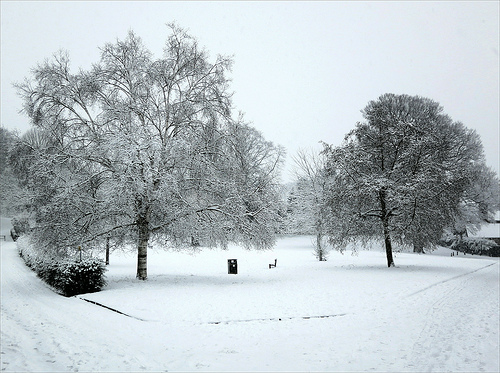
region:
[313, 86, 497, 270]
tree covered with snow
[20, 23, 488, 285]
two trees covered with snow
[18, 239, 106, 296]
low shrub with snow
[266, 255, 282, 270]
park bench in snow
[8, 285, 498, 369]
snow on the ground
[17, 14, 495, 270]
two trees in winter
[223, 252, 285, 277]
trash cans and bench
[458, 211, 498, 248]
slanted roof covered with snow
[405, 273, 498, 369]
tracks in the snow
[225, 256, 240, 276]
dark objects with white labels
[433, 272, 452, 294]
part of the snow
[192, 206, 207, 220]
part of a branch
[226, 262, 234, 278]
part of a speaker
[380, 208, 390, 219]
part of a branch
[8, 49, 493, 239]
The trees are bare.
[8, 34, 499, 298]
The trees are snow covered.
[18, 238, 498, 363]
The ground is snow covered.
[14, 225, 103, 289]
The bushes are snow covered.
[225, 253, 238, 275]
The trash can is in the snow.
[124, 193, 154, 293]
The trunk is black.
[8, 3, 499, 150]
The sky is cloudy.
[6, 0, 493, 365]
No one is out.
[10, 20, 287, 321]
The tree is tall.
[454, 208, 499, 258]
The house is in the back.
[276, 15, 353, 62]
sky above the land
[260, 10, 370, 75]
sky with no clouds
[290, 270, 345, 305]
snow on the ground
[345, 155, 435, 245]
tree in the photo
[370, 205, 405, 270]
branch of the tree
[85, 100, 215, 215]
many branches on the tree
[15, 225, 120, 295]
bush on the ground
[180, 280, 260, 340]
light hitting the ground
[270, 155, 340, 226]
trees in the distance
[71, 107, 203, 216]
snow on the tree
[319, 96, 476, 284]
a tree with no leaves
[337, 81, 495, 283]
a tree with snow on the branches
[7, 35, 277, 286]
a tree with no leaves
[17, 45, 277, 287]
a tree with snow on the branches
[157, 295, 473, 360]
snow on the ground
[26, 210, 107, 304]
a shrub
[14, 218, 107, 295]
a shrub with snow on it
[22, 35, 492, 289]
two snow-covered trees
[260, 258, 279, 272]
a park bench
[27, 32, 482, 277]
two trees without leaves